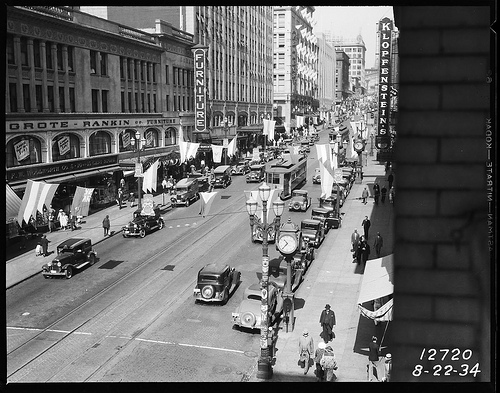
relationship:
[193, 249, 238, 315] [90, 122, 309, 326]
vehicle in road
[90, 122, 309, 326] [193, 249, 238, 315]
road has vehicle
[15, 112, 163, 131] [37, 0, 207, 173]
sign on buildiong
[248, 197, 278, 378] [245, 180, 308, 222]
post of lamp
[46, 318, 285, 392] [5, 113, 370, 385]
line across road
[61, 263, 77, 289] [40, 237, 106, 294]
tire on car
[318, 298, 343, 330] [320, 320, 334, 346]
man with suit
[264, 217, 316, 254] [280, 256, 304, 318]
clock on pole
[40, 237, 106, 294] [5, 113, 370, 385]
car on road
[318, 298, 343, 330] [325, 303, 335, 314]
man has hat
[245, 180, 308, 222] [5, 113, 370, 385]
lamp on road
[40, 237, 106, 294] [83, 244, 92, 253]
car has window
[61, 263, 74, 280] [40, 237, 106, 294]
tire on car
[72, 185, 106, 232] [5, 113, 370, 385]
flag on road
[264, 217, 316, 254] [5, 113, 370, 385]
clock on road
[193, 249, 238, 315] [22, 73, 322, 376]
vehicle on road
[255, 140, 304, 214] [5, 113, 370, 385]
trolley in road